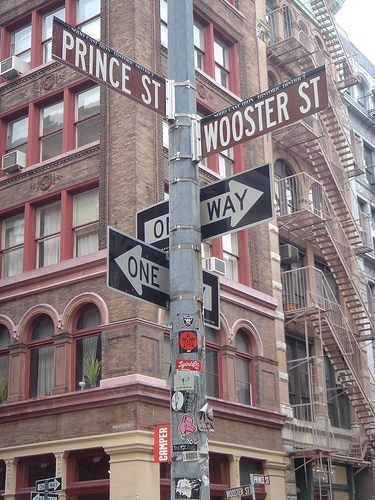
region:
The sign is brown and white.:
[39, 16, 183, 117]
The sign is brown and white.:
[196, 64, 343, 159]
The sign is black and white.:
[131, 155, 286, 246]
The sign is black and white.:
[90, 225, 229, 326]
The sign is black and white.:
[31, 471, 66, 493]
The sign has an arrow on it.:
[33, 472, 69, 492]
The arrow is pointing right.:
[31, 471, 64, 495]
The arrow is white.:
[31, 473, 65, 494]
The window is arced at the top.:
[65, 288, 115, 396]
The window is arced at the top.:
[13, 296, 64, 409]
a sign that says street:
[289, 86, 348, 121]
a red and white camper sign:
[155, 423, 170, 465]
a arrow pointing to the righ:
[49, 480, 72, 494]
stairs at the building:
[350, 365, 363, 408]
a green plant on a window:
[80, 354, 119, 392]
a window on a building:
[32, 351, 72, 373]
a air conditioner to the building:
[1, 143, 42, 185]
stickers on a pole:
[176, 417, 214, 456]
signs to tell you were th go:
[230, 475, 271, 493]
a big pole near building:
[164, 307, 214, 363]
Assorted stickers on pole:
[171, 312, 213, 498]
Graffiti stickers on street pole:
[170, 313, 215, 499]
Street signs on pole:
[50, 15, 329, 331]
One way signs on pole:
[105, 160, 278, 326]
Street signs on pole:
[48, 11, 325, 155]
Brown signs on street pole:
[49, 13, 330, 163]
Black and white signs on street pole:
[108, 161, 276, 328]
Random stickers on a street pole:
[166, 309, 216, 499]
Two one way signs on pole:
[105, 161, 275, 331]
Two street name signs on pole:
[49, 15, 330, 161]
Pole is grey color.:
[161, 66, 206, 374]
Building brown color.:
[8, 187, 124, 405]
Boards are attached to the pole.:
[89, 29, 260, 321]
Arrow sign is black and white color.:
[109, 184, 261, 329]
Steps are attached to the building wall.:
[269, 45, 370, 303]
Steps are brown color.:
[285, 113, 372, 419]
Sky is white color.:
[343, 6, 374, 46]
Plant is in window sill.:
[73, 357, 112, 395]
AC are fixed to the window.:
[4, 55, 28, 174]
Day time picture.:
[35, 189, 322, 486]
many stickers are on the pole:
[171, 314, 210, 498]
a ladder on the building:
[284, 264, 374, 455]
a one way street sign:
[105, 223, 225, 326]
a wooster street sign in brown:
[201, 70, 332, 150]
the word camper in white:
[151, 427, 170, 463]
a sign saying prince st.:
[50, 15, 171, 122]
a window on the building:
[66, 189, 113, 259]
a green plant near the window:
[77, 356, 103, 391]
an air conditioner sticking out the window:
[1, 150, 29, 170]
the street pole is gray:
[163, 0, 205, 498]